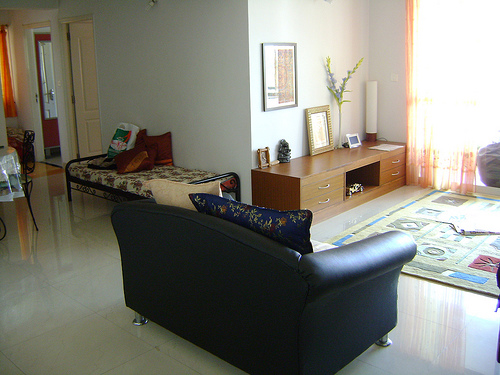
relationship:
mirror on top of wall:
[262, 42, 300, 110] [249, 4, 383, 165]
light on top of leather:
[395, 234, 418, 250] [112, 181, 419, 375]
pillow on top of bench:
[115, 146, 161, 175] [64, 149, 243, 209]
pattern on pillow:
[252, 209, 292, 238] [190, 192, 316, 252]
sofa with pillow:
[112, 181, 419, 375] [190, 192, 316, 252]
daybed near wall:
[64, 149, 243, 209] [95, 7, 249, 175]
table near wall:
[251, 141, 407, 215] [249, 4, 383, 165]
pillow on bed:
[115, 146, 161, 175] [64, 149, 243, 209]